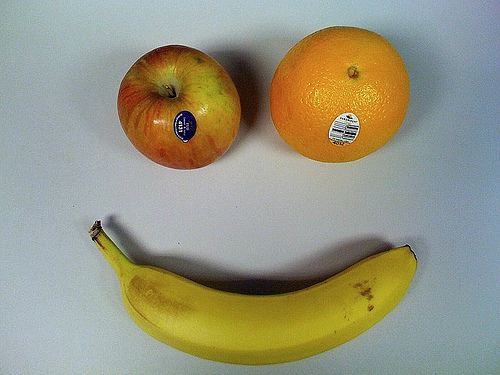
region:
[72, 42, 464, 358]
three pieces of fruit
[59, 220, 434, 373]
one banana in the photo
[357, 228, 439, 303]
end of the banana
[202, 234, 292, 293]
shadow on the table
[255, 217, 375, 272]
shadow of a banana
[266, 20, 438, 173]
orange piece of fruit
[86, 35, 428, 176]
two round pieces of fruit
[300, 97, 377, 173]
sticker on the fruit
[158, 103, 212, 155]
blue sticker on the fruit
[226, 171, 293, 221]
white table under food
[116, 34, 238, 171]
a red colored apple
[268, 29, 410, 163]
a small navel orange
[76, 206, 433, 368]
a ripe yellow banana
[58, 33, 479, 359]
fruit arranged to look like a happy face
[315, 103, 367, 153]
barcode sticker on rind of orange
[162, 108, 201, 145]
information sticker on an apple peel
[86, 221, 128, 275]
stem of a banana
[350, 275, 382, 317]
slight bruise on banana peel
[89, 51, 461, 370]
assorted picked fresh fruit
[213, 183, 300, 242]
white table surface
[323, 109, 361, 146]
The sticker is white.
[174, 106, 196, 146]
The sticker is blue.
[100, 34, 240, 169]
The apple is red.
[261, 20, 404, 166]
The orange is orange.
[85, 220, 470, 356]
The banana is yellow.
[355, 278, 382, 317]
A brown spot on the banana.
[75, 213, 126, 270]
The stem is brown.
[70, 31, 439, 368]
The fruit is on the table.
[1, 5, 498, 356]
The table is white.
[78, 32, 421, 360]
The fruit looks like a smily face.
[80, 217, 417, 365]
Yellow Ripe Banana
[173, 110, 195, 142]
Small Blue Information Sticker On The Apple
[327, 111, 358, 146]
Small Scanner Sticker on the orange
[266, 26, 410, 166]
Juicy Bright Orange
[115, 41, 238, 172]
Light Red and Yellow Apple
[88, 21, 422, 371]
All the fruit makes a smiley face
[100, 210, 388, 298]
Shadow made by the banana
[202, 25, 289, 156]
Dark and light shadows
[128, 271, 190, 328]
Small Bruise on the top of the banana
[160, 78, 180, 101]
Small Apple Stem On Top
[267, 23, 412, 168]
An orange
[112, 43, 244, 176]
An apple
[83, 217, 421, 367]
A banana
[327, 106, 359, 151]
A white and orange sticker on an orange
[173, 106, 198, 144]
A purple and white sticker on an apple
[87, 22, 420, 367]
some fruits arranged to look like a smiley face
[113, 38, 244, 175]
A small red apple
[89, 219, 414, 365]
A long yellow banana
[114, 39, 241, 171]
a red apple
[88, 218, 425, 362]
a yellow banana